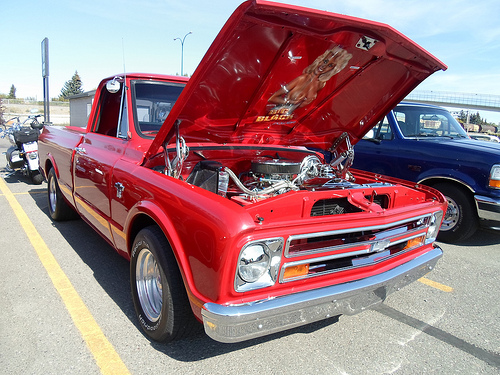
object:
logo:
[370, 238, 391, 253]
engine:
[200, 140, 380, 213]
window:
[86, 83, 128, 140]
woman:
[263, 43, 351, 124]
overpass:
[402, 83, 499, 112]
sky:
[0, 0, 498, 126]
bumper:
[201, 244, 442, 344]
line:
[0, 178, 134, 375]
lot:
[1, 144, 498, 372]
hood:
[138, 1, 448, 169]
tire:
[128, 226, 202, 343]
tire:
[47, 167, 81, 221]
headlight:
[422, 211, 444, 246]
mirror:
[103, 75, 123, 95]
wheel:
[422, 182, 481, 244]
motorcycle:
[0, 113, 46, 184]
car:
[350, 100, 500, 243]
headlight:
[234, 238, 285, 291]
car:
[38, 0, 446, 344]